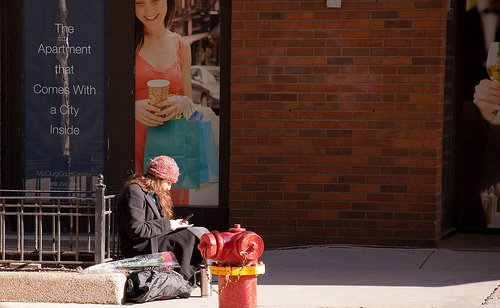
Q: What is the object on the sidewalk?
A: Fire hydrant.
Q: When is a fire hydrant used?
A: Fire.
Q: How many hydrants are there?
A: 1.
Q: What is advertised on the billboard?
A: Apartment.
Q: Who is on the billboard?
A: A woman with a cup.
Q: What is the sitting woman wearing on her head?
A: A beanie.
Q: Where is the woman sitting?
A: On a ledge.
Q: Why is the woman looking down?
A: Looking at phone.